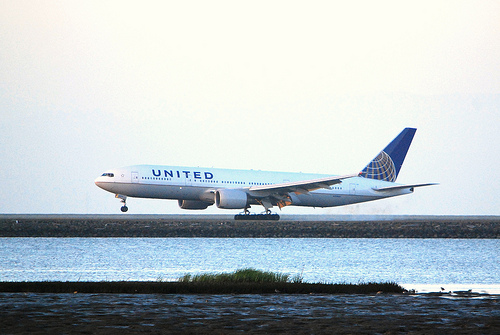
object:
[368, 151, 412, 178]
logo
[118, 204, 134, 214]
landing gear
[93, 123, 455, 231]
plane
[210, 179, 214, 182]
windows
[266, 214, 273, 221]
wheels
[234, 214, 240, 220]
landing gear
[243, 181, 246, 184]
windows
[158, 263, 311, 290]
sea grass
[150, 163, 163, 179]
letters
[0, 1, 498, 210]
sky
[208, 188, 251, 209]
wing engine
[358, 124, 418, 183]
tail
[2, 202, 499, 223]
runway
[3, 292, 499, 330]
space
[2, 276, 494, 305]
riverbank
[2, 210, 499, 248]
landscape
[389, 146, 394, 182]
lines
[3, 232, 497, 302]
water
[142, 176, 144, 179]
passenger windows